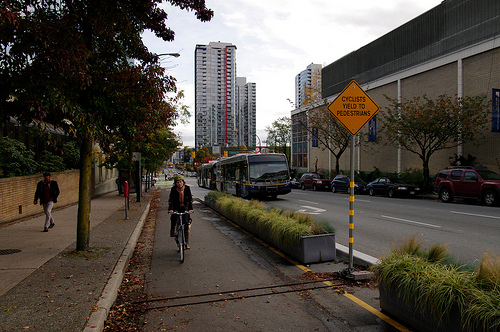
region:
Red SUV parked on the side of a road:
[433, 167, 498, 209]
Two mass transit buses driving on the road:
[189, 150, 294, 196]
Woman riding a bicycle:
[167, 171, 194, 264]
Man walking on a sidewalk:
[30, 166, 61, 234]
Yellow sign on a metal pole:
[325, 80, 380, 268]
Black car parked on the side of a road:
[361, 173, 421, 200]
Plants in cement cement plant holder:
[203, 186, 339, 267]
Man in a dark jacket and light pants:
[30, 169, 61, 231]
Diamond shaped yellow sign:
[325, 78, 380, 136]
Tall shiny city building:
[189, 36, 259, 155]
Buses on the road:
[194, 152, 293, 202]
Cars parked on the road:
[290, 167, 497, 208]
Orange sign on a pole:
[327, 78, 379, 136]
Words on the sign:
[335, 93, 369, 116]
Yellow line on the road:
[199, 195, 409, 330]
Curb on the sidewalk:
[40, 177, 157, 329]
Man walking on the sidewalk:
[32, 169, 58, 231]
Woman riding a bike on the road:
[166, 171, 193, 265]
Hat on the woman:
[171, 171, 185, 182]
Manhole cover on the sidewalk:
[1, 245, 21, 255]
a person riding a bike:
[166, 174, 214, 261]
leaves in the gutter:
[120, 297, 132, 330]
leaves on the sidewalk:
[33, 266, 85, 303]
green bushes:
[257, 209, 287, 235]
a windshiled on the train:
[248, 157, 286, 182]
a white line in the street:
[379, 207, 440, 232]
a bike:
[176, 225, 193, 258]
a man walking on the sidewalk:
[33, 172, 68, 232]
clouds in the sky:
[236, 17, 315, 51]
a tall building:
[193, 47, 244, 144]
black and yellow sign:
[325, 89, 383, 152]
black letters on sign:
[328, 77, 365, 147]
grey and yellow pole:
[334, 126, 366, 297]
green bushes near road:
[212, 162, 303, 246]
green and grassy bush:
[202, 189, 332, 244]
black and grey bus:
[202, 154, 289, 203]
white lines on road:
[287, 202, 482, 263]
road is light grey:
[346, 205, 494, 243]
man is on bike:
[169, 174, 190, 253]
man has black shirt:
[165, 164, 192, 228]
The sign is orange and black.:
[323, 73, 388, 293]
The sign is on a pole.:
[321, 66, 388, 286]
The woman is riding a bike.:
[153, 141, 226, 281]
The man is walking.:
[27, 158, 84, 258]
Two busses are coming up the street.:
[186, 133, 348, 259]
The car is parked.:
[296, 158, 333, 198]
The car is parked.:
[328, 164, 370, 201]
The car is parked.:
[360, 160, 425, 206]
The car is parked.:
[418, 149, 498, 216]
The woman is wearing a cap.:
[155, 163, 203, 266]